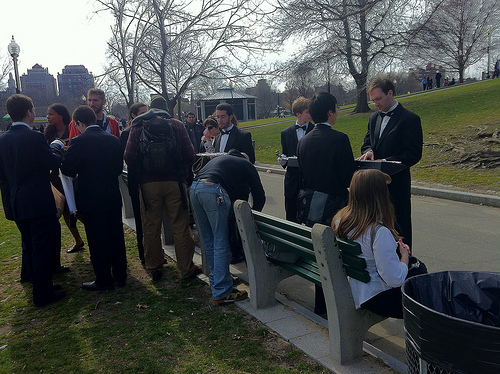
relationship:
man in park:
[356, 79, 423, 277] [7, 63, 494, 373]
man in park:
[117, 97, 201, 289] [7, 63, 494, 373]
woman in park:
[329, 168, 431, 314] [7, 63, 494, 373]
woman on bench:
[329, 168, 431, 314] [233, 207, 387, 313]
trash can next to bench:
[400, 268, 499, 371] [233, 207, 387, 313]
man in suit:
[356, 79, 423, 277] [360, 111, 422, 260]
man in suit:
[5, 94, 72, 312] [1, 122, 71, 310]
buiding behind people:
[21, 66, 59, 131] [7, 89, 142, 303]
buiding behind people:
[58, 64, 104, 120] [7, 89, 142, 303]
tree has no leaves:
[264, 3, 402, 126] [310, 13, 341, 28]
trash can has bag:
[400, 268, 499, 371] [404, 270, 498, 344]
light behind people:
[8, 33, 29, 139] [7, 89, 142, 303]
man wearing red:
[69, 84, 123, 152] [70, 126, 76, 139]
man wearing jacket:
[69, 84, 123, 152] [69, 110, 124, 154]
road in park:
[212, 159, 497, 367] [7, 63, 494, 373]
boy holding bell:
[282, 100, 316, 217] [273, 152, 290, 167]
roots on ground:
[446, 132, 497, 179] [329, 79, 499, 189]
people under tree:
[412, 63, 457, 98] [402, 2, 499, 90]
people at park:
[7, 89, 142, 303] [7, 63, 494, 373]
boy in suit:
[282, 100, 316, 217] [276, 123, 322, 229]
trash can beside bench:
[400, 268, 499, 371] [233, 207, 387, 313]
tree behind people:
[264, 3, 402, 126] [7, 89, 142, 303]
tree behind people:
[97, 0, 172, 133] [7, 89, 142, 303]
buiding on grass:
[194, 79, 261, 126] [239, 78, 498, 180]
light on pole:
[10, 38, 20, 56] [8, 33, 30, 147]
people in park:
[7, 89, 142, 303] [7, 63, 494, 373]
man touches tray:
[356, 79, 423, 277] [357, 154, 405, 176]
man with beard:
[69, 84, 123, 152] [87, 100, 105, 117]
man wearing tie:
[356, 79, 423, 277] [379, 111, 392, 118]